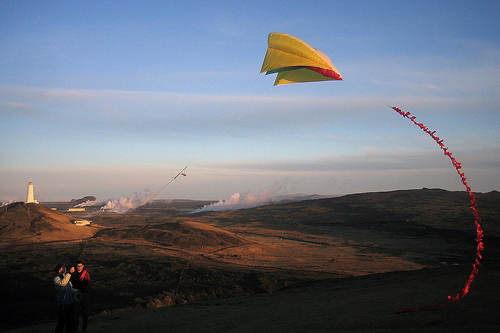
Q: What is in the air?
A: A kite.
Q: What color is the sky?
A: Blue.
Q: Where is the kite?
A: In the air.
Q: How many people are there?
A: Two.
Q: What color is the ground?
A: Brown.